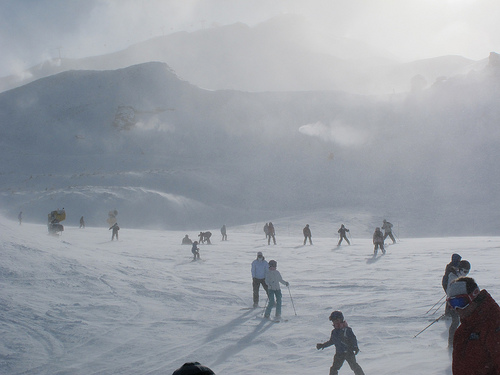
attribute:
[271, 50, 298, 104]
snow — white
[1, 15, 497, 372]
snow — white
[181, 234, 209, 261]
children — small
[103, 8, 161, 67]
snow — white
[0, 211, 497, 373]
snow — white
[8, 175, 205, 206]
snow — white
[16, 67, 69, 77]
snow — white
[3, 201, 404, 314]
group — large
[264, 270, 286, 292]
coat — light colored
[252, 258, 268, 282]
coat — light colored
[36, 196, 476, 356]
group — large, people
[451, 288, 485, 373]
coat — black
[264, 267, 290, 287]
coat — white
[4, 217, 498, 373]
area — snowy